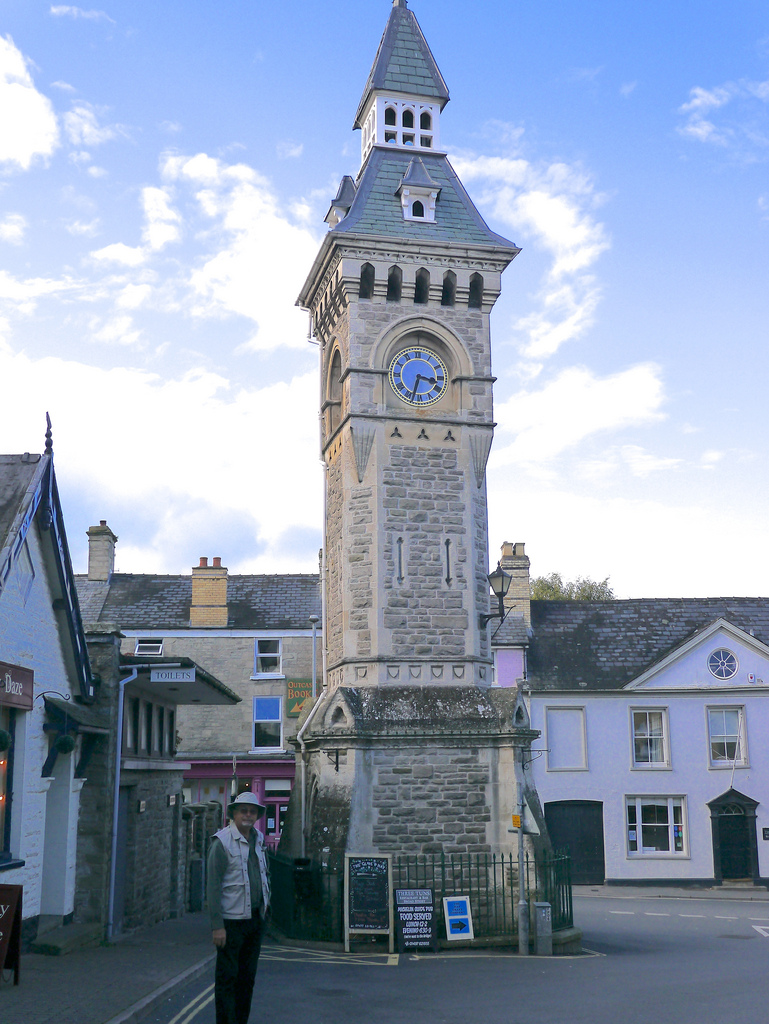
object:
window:
[254, 696, 281, 746]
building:
[73, 520, 533, 856]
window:
[256, 640, 281, 673]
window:
[134, 640, 162, 657]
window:
[265, 803, 277, 835]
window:
[265, 778, 291, 797]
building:
[75, 622, 245, 940]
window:
[127, 696, 134, 748]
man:
[206, 791, 273, 1023]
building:
[1, 411, 97, 955]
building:
[73, 518, 767, 885]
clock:
[388, 345, 450, 408]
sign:
[442, 895, 474, 941]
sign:
[344, 852, 395, 953]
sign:
[393, 887, 439, 953]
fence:
[269, 843, 575, 942]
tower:
[274, 0, 557, 937]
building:
[526, 595, 769, 890]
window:
[628, 704, 670, 771]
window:
[707, 703, 752, 771]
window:
[622, 792, 691, 860]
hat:
[226, 791, 267, 819]